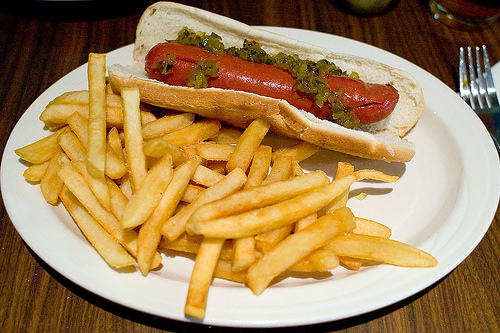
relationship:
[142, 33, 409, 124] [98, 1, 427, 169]
hot dog in a bun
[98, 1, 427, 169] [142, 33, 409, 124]
bun holding hot dog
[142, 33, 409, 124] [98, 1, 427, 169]
hot dog in bun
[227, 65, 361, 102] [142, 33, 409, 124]
light reflecting on hot dog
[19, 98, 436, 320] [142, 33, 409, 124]
fries next to hot dog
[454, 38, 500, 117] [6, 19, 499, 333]
fork next to palte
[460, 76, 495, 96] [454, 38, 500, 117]
light reflecting on fork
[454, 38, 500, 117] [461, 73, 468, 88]
fork has stain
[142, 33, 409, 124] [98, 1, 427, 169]
hotdog on a bun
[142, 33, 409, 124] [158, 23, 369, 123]
hotdog has relish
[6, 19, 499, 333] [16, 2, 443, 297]
plate in use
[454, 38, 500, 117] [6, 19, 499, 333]
fork next to plate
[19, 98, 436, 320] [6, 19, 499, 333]
fries are on plate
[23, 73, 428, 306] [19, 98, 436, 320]
french fries in a pile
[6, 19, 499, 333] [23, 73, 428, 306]
plate has french fries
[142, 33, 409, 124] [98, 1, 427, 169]
hotdog in a bun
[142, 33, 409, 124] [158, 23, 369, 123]
hotdog with relish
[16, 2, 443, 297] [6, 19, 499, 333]
food in plate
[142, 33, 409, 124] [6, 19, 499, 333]
hotdog on plate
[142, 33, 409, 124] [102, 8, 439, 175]
relish on dog